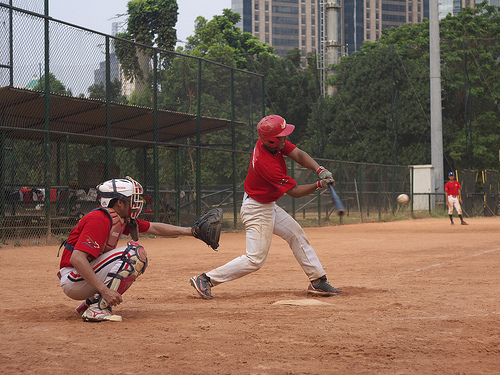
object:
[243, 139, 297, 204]
red shirt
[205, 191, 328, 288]
grey slacks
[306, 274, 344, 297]
black shoes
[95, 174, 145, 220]
white helmet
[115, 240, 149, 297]
chest guard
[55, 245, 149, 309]
white pants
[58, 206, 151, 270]
red shirt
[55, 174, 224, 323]
catcher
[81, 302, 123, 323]
white shoes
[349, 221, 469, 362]
dirt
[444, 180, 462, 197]
shirt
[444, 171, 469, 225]
man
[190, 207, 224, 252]
catcher's mitt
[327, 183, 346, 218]
bat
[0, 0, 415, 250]
fence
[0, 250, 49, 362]
dirt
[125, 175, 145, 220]
mask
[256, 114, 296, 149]
helmet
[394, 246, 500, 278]
lines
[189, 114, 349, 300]
baseball players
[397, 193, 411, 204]
ball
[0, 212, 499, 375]
field